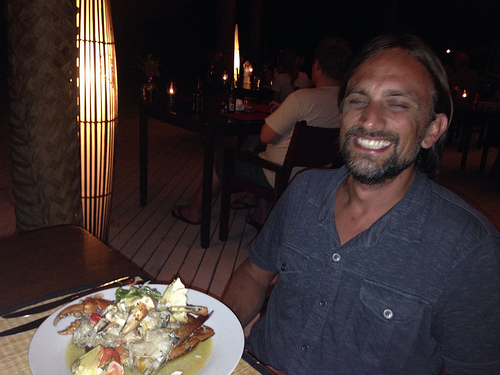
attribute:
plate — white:
[26, 273, 246, 373]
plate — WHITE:
[218, 335, 248, 357]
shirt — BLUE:
[312, 255, 395, 368]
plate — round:
[31, 284, 247, 374]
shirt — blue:
[241, 163, 499, 372]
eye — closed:
[347, 97, 367, 107]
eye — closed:
[388, 95, 408, 113]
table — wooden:
[0, 223, 286, 374]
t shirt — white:
[256, 89, 344, 193]